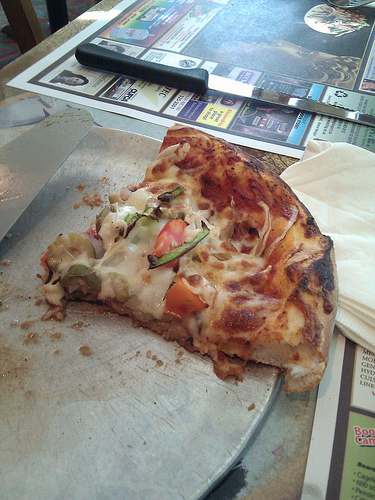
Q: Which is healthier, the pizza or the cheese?
A: The cheese is healthier than the pizza.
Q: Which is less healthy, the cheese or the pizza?
A: The pizza is less healthy than the cheese.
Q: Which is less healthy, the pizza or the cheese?
A: The pizza is less healthy than the cheese.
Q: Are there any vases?
A: No, there are no vases.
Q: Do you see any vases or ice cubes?
A: No, there are no vases or ice cubes.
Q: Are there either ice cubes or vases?
A: No, there are no vases or ice cubes.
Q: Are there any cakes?
A: No, there are no cakes.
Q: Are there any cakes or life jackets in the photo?
A: No, there are no cakes or life jackets.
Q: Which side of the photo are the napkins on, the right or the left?
A: The napkins are on the right of the image.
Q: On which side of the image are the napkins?
A: The napkins are on the right of the image.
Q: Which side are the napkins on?
A: The napkins are on the right of the image.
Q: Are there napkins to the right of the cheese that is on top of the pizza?
A: Yes, there are napkins to the right of the cheese.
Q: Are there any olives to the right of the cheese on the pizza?
A: No, there are napkins to the right of the cheese.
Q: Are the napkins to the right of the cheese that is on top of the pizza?
A: Yes, the napkins are to the right of the cheese.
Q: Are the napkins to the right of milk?
A: No, the napkins are to the right of the cheese.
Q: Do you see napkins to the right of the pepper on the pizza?
A: Yes, there are napkins to the right of the pepper.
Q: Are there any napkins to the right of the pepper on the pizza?
A: Yes, there are napkins to the right of the pepper.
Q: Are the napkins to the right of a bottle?
A: No, the napkins are to the right of the pepper.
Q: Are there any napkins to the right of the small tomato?
A: Yes, there are napkins to the right of the tomato.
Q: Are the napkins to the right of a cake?
A: No, the napkins are to the right of a tomato.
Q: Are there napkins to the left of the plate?
A: No, the napkins are to the right of the plate.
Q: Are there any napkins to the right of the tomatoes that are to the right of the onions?
A: Yes, there are napkins to the right of the tomatoes.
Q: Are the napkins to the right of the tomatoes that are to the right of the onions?
A: Yes, the napkins are to the right of the tomatoes.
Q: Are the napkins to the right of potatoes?
A: No, the napkins are to the right of the tomatoes.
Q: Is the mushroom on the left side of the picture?
A: Yes, the mushroom is on the left of the image.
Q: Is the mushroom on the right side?
A: No, the mushroom is on the left of the image.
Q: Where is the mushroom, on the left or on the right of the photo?
A: The mushroom is on the left of the image.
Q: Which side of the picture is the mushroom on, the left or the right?
A: The mushroom is on the left of the image.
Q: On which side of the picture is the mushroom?
A: The mushroom is on the left of the image.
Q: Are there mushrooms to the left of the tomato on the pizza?
A: Yes, there is a mushroom to the left of the tomato.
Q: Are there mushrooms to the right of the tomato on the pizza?
A: No, the mushroom is to the left of the tomato.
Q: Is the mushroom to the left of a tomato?
A: Yes, the mushroom is to the left of a tomato.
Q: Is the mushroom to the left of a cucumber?
A: No, the mushroom is to the left of a tomato.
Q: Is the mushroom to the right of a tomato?
A: No, the mushroom is to the left of a tomato.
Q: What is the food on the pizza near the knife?
A: The food is a mushroom.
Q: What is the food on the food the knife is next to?
A: The food is a mushroom.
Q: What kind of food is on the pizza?
A: The food is a mushroom.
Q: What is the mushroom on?
A: The mushroom is on the pizza.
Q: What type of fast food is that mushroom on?
A: The mushroom is on the pizza.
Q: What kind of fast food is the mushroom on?
A: The mushroom is on the pizza.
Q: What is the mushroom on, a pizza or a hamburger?
A: The mushroom is on a pizza.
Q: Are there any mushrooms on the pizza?
A: Yes, there is a mushroom on the pizza.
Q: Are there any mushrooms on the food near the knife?
A: Yes, there is a mushroom on the pizza.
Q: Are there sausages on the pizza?
A: No, there is a mushroom on the pizza.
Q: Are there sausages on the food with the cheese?
A: No, there is a mushroom on the pizza.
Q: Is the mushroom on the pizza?
A: Yes, the mushroom is on the pizza.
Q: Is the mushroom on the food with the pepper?
A: Yes, the mushroom is on the pizza.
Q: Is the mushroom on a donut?
A: No, the mushroom is on the pizza.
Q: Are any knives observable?
A: Yes, there is a knife.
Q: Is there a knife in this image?
A: Yes, there is a knife.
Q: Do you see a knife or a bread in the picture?
A: Yes, there is a knife.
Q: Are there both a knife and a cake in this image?
A: No, there is a knife but no cakes.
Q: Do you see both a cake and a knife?
A: No, there is a knife but no cakes.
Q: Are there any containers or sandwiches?
A: No, there are no sandwiches or containers.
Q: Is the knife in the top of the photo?
A: Yes, the knife is in the top of the image.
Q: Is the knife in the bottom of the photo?
A: No, the knife is in the top of the image.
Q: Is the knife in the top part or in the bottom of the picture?
A: The knife is in the top of the image.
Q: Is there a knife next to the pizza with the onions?
A: Yes, there is a knife next to the pizza.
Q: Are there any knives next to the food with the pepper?
A: Yes, there is a knife next to the pizza.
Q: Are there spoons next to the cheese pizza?
A: No, there is a knife next to the pizza.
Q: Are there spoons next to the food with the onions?
A: No, there is a knife next to the pizza.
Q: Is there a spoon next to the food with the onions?
A: No, there is a knife next to the pizza.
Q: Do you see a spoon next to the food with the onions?
A: No, there is a knife next to the pizza.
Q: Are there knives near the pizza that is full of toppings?
A: Yes, there is a knife near the pizza.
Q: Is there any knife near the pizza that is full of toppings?
A: Yes, there is a knife near the pizza.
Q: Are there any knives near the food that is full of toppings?
A: Yes, there is a knife near the pizza.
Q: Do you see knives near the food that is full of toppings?
A: Yes, there is a knife near the pizza.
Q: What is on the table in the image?
A: The knife is on the table.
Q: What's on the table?
A: The knife is on the table.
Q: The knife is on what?
A: The knife is on the table.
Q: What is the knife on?
A: The knife is on the table.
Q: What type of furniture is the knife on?
A: The knife is on the table.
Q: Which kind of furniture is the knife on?
A: The knife is on the table.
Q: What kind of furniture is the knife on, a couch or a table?
A: The knife is on a table.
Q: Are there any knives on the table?
A: Yes, there is a knife on the table.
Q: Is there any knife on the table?
A: Yes, there is a knife on the table.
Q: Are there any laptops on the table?
A: No, there is a knife on the table.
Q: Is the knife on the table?
A: Yes, the knife is on the table.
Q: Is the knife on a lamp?
A: No, the knife is on the table.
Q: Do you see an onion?
A: Yes, there are onions.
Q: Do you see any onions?
A: Yes, there are onions.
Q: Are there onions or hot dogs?
A: Yes, there are onions.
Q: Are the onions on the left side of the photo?
A: Yes, the onions are on the left of the image.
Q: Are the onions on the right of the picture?
A: No, the onions are on the left of the image.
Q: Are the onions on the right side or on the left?
A: The onions are on the left of the image.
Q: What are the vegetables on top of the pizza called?
A: The vegetables are onions.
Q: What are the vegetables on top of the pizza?
A: The vegetables are onions.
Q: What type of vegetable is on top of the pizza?
A: The vegetables are onions.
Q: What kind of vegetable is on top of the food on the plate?
A: The vegetables are onions.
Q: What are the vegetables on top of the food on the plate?
A: The vegetables are onions.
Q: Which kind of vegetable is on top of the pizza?
A: The vegetables are onions.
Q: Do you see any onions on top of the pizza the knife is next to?
A: Yes, there are onions on top of the pizza.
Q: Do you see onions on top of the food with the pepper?
A: Yes, there are onions on top of the pizza.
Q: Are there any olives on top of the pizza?
A: No, there are onions on top of the pizza.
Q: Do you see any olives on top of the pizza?
A: No, there are onions on top of the pizza.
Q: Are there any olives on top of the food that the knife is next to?
A: No, there are onions on top of the pizza.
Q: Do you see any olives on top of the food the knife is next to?
A: No, there are onions on top of the pizza.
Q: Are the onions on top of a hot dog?
A: No, the onions are on top of the pizza.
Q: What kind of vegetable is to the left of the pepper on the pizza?
A: The vegetables are onions.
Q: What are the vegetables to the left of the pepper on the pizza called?
A: The vegetables are onions.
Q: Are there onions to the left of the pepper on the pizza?
A: Yes, there are onions to the left of the pepper.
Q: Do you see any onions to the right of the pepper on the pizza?
A: No, the onions are to the left of the pepper.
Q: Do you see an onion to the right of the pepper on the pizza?
A: No, the onions are to the left of the pepper.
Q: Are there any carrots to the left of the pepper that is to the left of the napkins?
A: No, there are onions to the left of the pepper.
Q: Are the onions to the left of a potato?
A: No, the onions are to the left of a pepper.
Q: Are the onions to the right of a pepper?
A: No, the onions are to the left of a pepper.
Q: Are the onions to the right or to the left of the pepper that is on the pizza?
A: The onions are to the left of the pepper.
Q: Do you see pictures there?
A: No, there are no pictures.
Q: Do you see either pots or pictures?
A: No, there are no pictures or pots.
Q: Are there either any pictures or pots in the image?
A: No, there are no pictures or pots.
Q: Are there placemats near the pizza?
A: Yes, there is a placemat near the pizza.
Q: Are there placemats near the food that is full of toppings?
A: Yes, there is a placemat near the pizza.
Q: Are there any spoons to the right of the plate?
A: No, there is a placemat to the right of the plate.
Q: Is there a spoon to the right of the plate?
A: No, there is a placemat to the right of the plate.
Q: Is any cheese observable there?
A: Yes, there is cheese.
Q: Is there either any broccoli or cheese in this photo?
A: Yes, there is cheese.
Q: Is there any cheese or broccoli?
A: Yes, there is cheese.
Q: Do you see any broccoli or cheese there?
A: Yes, there is cheese.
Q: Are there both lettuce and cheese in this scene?
A: No, there is cheese but no lettuce.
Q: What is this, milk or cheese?
A: This is cheese.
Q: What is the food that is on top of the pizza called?
A: The food is cheese.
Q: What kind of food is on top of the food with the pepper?
A: The food is cheese.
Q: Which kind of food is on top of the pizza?
A: The food is cheese.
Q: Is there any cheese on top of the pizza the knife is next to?
A: Yes, there is cheese on top of the pizza.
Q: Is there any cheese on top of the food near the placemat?
A: Yes, there is cheese on top of the pizza.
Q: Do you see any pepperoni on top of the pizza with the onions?
A: No, there is cheese on top of the pizza.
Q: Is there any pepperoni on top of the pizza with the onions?
A: No, there is cheese on top of the pizza.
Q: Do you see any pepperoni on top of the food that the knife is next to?
A: No, there is cheese on top of the pizza.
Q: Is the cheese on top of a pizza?
A: Yes, the cheese is on top of a pizza.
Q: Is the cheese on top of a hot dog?
A: No, the cheese is on top of a pizza.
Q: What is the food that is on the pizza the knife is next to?
A: The food is cheese.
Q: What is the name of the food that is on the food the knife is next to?
A: The food is cheese.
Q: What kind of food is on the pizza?
A: The food is cheese.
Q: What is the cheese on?
A: The cheese is on the pizza.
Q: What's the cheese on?
A: The cheese is on the pizza.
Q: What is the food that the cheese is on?
A: The food is a pizza.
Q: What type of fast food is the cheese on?
A: The cheese is on the pizza.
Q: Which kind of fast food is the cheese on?
A: The cheese is on the pizza.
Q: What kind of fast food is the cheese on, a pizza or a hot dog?
A: The cheese is on a pizza.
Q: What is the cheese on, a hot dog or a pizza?
A: The cheese is on a pizza.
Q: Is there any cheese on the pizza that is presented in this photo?
A: Yes, there is cheese on the pizza.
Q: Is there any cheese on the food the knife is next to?
A: Yes, there is cheese on the pizza.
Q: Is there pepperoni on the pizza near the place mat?
A: No, there is cheese on the pizza.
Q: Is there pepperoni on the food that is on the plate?
A: No, there is cheese on the pizza.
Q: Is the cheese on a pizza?
A: Yes, the cheese is on a pizza.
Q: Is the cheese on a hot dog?
A: No, the cheese is on a pizza.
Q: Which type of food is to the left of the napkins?
A: The food is cheese.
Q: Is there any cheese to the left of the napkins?
A: Yes, there is cheese to the left of the napkins.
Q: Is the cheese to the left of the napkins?
A: Yes, the cheese is to the left of the napkins.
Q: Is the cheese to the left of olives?
A: No, the cheese is to the left of the napkins.